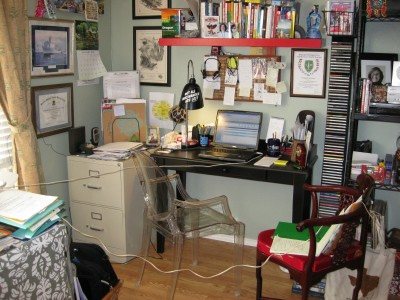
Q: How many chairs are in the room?
A: Two.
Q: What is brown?
A: Chair on right.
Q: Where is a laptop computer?
A: On the desk.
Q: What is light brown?
A: Floor.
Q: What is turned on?
A: Computer screen.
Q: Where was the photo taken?
A: In a room.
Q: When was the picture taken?
A: Daytime.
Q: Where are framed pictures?
A: On the wall.